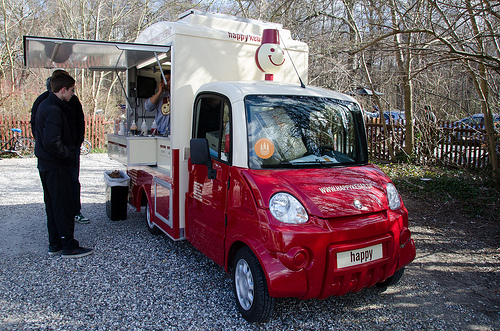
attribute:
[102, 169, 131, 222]
trash — black, white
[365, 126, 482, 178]
fence — brown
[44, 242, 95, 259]
shoes — black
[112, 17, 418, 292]
small truck — white, red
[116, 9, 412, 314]
truck — food truck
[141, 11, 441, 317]
truck — food truck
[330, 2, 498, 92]
trees — bare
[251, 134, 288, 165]
decal — orange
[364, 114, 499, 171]
fence — wooden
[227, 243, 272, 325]
tire — spoked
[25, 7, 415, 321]
truck — red, white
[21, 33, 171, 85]
side door — open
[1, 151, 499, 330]
road — gravel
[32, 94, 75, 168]
shirt — black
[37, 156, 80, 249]
pants — black